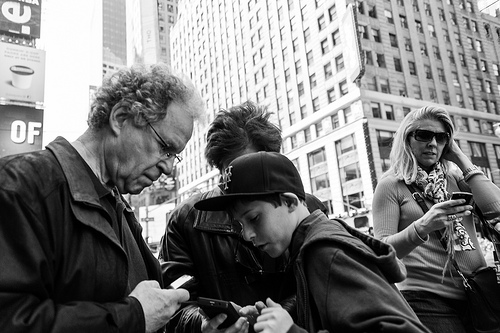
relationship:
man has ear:
[2, 63, 191, 332] [110, 100, 134, 135]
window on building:
[333, 130, 357, 156] [169, 6, 499, 235]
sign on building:
[336, 2, 368, 88] [169, 6, 499, 235]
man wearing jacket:
[2, 63, 191, 332] [2, 136, 166, 330]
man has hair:
[2, 63, 191, 332] [86, 60, 204, 129]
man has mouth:
[2, 63, 191, 332] [141, 170, 155, 186]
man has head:
[2, 63, 191, 332] [87, 64, 202, 199]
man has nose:
[2, 63, 191, 332] [157, 158, 176, 176]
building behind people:
[169, 6, 499, 235] [2, 62, 498, 332]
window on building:
[327, 3, 339, 24] [169, 6, 499, 235]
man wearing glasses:
[2, 63, 191, 332] [141, 110, 186, 167]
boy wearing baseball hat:
[191, 148, 433, 332] [193, 149, 307, 212]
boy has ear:
[191, 148, 433, 332] [282, 189, 299, 212]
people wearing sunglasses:
[368, 103, 499, 332] [410, 127, 451, 146]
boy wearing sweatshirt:
[191, 148, 433, 332] [289, 209, 431, 333]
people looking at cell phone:
[368, 103, 499, 332] [449, 190, 472, 204]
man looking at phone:
[2, 63, 191, 332] [162, 272, 196, 291]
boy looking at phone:
[191, 148, 433, 332] [197, 293, 238, 321]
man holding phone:
[2, 63, 191, 332] [162, 272, 196, 291]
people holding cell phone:
[368, 103, 499, 332] [449, 190, 472, 204]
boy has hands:
[191, 148, 433, 332] [255, 298, 297, 333]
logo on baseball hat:
[219, 163, 236, 191] [193, 149, 307, 212]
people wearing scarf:
[368, 103, 499, 332] [413, 162, 477, 253]